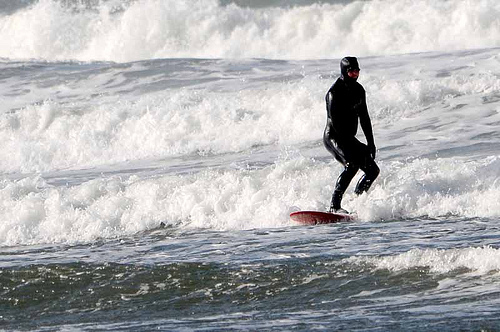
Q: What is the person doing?
A: Surfing.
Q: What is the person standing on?
A: Surfboard.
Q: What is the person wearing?
A: A wetsuit.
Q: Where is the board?
A: In water.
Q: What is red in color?
A: The board.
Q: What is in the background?
A: White wave.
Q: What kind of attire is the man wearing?
A: A wet suit.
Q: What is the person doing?
A: Surfing.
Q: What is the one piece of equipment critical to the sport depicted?
A: Surfboard.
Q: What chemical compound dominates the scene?
A: Water.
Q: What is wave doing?
A: Crashing.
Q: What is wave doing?
A: Building up.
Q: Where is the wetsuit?
A: On man.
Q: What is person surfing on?
A: Waves.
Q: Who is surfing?
A: Surfer.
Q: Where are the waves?
A: Ocean.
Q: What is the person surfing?
A: Waves.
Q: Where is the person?
A: In waves.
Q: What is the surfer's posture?
A: Slightly crouched.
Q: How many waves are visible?
A: Four.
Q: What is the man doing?
A: Surfing.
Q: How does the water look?
A: Dark.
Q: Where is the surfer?
A: Ocean.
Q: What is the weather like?
A: Sunny.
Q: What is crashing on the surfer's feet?
A: Waves.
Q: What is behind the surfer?
A: Waves.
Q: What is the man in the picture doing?
A: He is surfing on water.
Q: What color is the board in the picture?
A: Red.